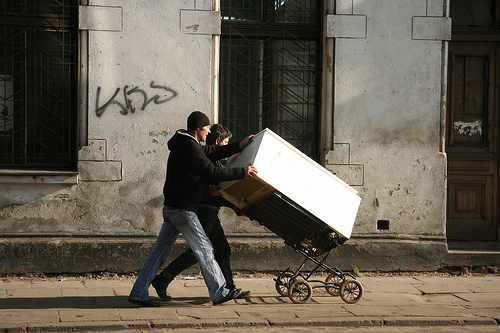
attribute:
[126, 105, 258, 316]
men — walking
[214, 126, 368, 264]
appliance — white, small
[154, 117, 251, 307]
men — walking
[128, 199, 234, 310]
jeans — blue, light blue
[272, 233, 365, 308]
cart — old, four-wheeled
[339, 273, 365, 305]
wheels — black, brown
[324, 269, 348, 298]
wheels — black, brown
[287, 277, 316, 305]
wheels — black, brown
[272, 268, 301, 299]
wheels — black, brown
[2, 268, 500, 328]
sidewalk — brick, brown, stoned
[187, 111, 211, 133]
hat — black, dark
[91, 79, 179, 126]
paint — black, graffiti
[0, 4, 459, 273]
wall — gray, concrete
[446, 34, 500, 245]
door — wood, brown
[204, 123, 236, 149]
hair — dark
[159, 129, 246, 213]
coat — black, long sleeved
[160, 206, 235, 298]
pants — dark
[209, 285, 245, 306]
shoes — black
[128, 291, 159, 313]
shoes — black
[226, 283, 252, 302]
shoes — brown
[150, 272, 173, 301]
shoes — brown